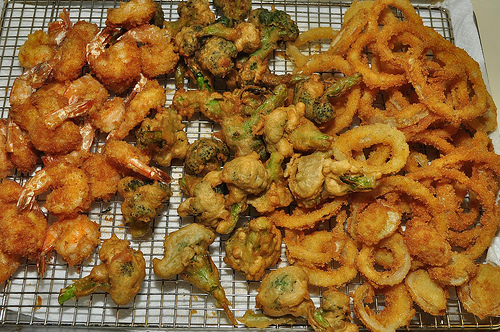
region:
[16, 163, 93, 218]
a piece of fried shrimp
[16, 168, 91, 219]
a hot and fried shrimp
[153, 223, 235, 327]
a piece of fried broccoli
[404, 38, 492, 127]
a fried onion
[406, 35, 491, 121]
an onion ring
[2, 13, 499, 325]
a cluster of fried food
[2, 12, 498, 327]
snacks that are fried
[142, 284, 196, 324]
a piece of the metal shelving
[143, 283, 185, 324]
a piece of the cooling rack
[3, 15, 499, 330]
tasty snacks to eat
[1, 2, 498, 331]
metal tray on paper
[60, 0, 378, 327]
tempura cooked broccoli pieces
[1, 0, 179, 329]
tempura cooked shrimp with tail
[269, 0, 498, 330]
tempura fried onion rings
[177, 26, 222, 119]
broccoli with tempura peeling off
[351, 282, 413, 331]
tempura batter peeling off onion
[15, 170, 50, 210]
shrimp tail sticking out of tempura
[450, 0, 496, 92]
paper towel to blot oil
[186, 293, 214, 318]
tempura batter crumbs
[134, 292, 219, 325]
wire tray grid with small holes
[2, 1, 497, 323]
fried food on a rack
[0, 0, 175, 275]
fried jumpo shrimp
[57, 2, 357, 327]
fried green broccolli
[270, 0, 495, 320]
fried white onion rings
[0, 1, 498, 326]
silver metal drying rack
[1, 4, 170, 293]
breaded shrimp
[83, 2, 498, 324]
vegetables that have been fried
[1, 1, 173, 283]
seafood that has been fried in oil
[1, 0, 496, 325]
wire drying rack over white paper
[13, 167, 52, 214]
shrimp tail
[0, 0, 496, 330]
wire rack under food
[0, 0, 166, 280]
fried shrimp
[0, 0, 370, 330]
fried broccoli next to fried shrimp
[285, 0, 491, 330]
onion rings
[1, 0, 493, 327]
fried food piled on wire rack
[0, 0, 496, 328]
silver wire rack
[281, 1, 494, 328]
pile of onion rings on rack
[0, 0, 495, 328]
shrimp, broccoli, and onion rings are breaded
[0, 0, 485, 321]
paper towels under wire rack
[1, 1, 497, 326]
white paper towels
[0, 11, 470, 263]
Fried food on a cooling rack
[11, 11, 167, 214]
Fried shrimp with tails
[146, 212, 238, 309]
Fried and breaded vegetable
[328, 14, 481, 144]
Golden fried onion rings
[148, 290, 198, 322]
Cooling rack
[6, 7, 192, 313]
White paper under a cooking rack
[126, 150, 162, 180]
Tail of a fried shrimp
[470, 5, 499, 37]
White counter holding cooked food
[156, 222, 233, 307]
Green broccoli fried in batter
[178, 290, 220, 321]
Crumbs from fried food under cooling rack